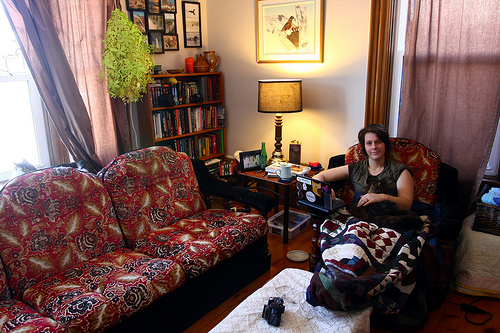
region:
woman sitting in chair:
[303, 122, 448, 238]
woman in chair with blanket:
[293, 125, 443, 311]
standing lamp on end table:
[247, 59, 313, 175]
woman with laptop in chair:
[288, 124, 420, 224]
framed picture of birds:
[244, 1, 337, 68]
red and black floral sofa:
[6, 147, 236, 323]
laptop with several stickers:
[284, 170, 351, 220]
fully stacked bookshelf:
[141, 41, 229, 158]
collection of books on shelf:
[142, 82, 231, 150]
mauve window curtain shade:
[1, 13, 119, 161]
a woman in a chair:
[286, 121, 461, 314]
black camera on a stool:
[246, 280, 300, 328]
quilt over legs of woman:
[274, 193, 441, 301]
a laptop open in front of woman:
[288, 168, 362, 220]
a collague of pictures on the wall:
[127, 3, 187, 62]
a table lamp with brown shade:
[251, 73, 304, 174]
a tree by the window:
[96, 2, 181, 189]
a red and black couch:
[6, 165, 281, 327]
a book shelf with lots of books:
[149, 68, 256, 193]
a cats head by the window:
[1, 149, 51, 190]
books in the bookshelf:
[123, 54, 248, 189]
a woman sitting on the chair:
[288, 100, 438, 330]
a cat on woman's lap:
[333, 175, 428, 235]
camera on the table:
[240, 285, 307, 332]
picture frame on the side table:
[221, 127, 310, 193]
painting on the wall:
[237, 6, 345, 71]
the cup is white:
[260, 152, 318, 194]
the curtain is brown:
[27, 38, 119, 150]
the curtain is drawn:
[2, 5, 159, 221]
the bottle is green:
[258, 134, 270, 172]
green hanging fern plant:
[98, 11, 150, 111]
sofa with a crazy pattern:
[37, 184, 222, 281]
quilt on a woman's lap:
[316, 208, 438, 299]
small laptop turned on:
[287, 171, 349, 217]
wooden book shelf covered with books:
[137, 68, 237, 163]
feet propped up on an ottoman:
[294, 261, 356, 331]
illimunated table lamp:
[253, 70, 308, 167]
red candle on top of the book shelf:
[176, 52, 203, 73]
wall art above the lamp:
[239, 3, 336, 76]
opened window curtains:
[7, 14, 128, 168]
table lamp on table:
[236, 69, 321, 181]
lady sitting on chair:
[317, 108, 433, 285]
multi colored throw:
[301, 170, 448, 331]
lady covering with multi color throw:
[299, 182, 467, 332]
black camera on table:
[244, 277, 286, 332]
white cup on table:
[267, 158, 309, 200]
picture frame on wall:
[240, 0, 354, 75]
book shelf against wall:
[118, 55, 265, 165]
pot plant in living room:
[83, 6, 188, 168]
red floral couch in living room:
[0, 140, 292, 331]